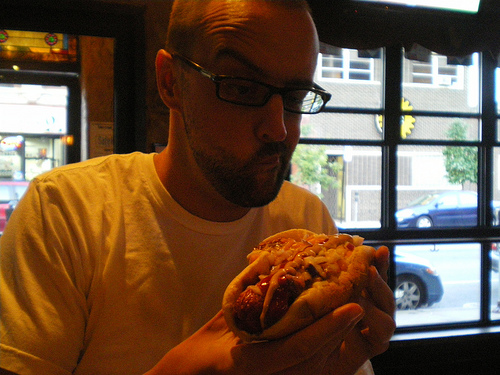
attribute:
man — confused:
[32, 32, 368, 363]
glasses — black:
[170, 51, 332, 120]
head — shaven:
[150, 7, 295, 209]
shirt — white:
[17, 140, 331, 365]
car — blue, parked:
[383, 179, 498, 231]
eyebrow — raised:
[206, 47, 253, 81]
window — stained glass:
[1, 28, 80, 77]